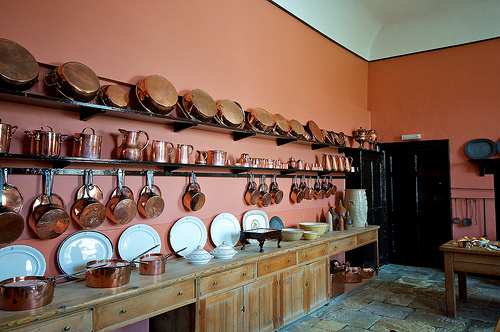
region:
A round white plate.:
[167, 215, 207, 255]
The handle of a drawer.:
[119, 307, 126, 314]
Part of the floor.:
[358, 302, 387, 327]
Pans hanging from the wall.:
[28, 169, 70, 238]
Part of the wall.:
[132, 19, 196, 59]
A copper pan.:
[136, 72, 179, 114]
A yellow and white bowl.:
[281, 227, 302, 241]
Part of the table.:
[446, 247, 462, 265]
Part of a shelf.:
[103, 159, 138, 165]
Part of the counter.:
[176, 267, 188, 275]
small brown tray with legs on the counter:
[238, 226, 285, 249]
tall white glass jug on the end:
[344, 187, 370, 228]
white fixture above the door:
[400, 132, 419, 139]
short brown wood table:
[441, 237, 498, 317]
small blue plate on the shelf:
[270, 214, 284, 229]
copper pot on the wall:
[181, 174, 203, 211]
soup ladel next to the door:
[451, 197, 459, 224]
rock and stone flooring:
[273, 262, 498, 331]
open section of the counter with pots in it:
[328, 244, 378, 295]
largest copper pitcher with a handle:
[116, 125, 154, 160]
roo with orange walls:
[1, 5, 496, 330]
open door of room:
[358, 137, 454, 271]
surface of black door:
[355, 150, 387, 268]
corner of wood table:
[441, 238, 497, 315]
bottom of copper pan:
[45, 61, 98, 103]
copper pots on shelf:
[0, 37, 378, 149]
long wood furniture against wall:
[0, 223, 381, 329]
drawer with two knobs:
[95, 281, 198, 327]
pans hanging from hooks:
[1, 170, 342, 237]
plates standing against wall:
[0, 212, 276, 290]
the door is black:
[382, 140, 452, 264]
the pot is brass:
[2, 276, 54, 309]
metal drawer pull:
[178, 289, 183, 294]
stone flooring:
[286, 264, 499, 330]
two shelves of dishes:
[1, 35, 354, 175]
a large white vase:
[345, 188, 369, 226]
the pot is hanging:
[184, 170, 204, 209]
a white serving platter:
[210, 213, 240, 250]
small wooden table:
[440, 237, 497, 317]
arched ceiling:
[367, 0, 492, 60]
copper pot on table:
[0, 270, 77, 319]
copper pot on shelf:
[80, 241, 160, 291]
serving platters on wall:
[0, 220, 243, 292]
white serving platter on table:
[0, 241, 50, 287]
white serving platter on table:
[45, 226, 122, 275]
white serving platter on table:
[117, 219, 169, 268]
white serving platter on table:
[206, 203, 247, 258]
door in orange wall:
[370, 136, 461, 276]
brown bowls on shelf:
[277, 221, 333, 247]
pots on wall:
[2, 31, 382, 159]